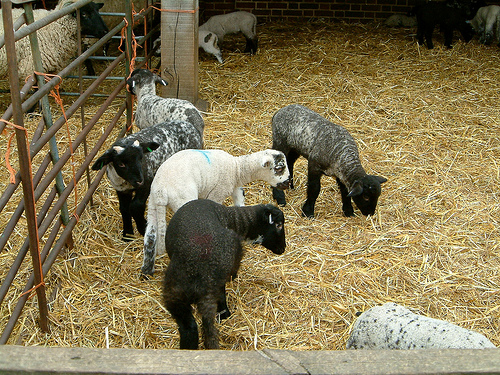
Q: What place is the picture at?
A: It is at the pen.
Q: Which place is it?
A: It is a pen.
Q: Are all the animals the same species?
A: No, there are both sheep and goats.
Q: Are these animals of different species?
A: Yes, they are sheep and goats.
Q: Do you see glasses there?
A: No, there are no glasses.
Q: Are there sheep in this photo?
A: Yes, there is a sheep.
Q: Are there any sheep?
A: Yes, there is a sheep.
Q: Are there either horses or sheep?
A: Yes, there is a sheep.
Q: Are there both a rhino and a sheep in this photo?
A: No, there is a sheep but no rhinos.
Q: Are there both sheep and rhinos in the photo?
A: No, there is a sheep but no rhinos.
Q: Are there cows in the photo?
A: No, there are no cows.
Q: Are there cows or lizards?
A: No, there are no cows or lizards.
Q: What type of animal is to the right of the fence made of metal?
A: The animal is a sheep.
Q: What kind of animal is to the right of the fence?
A: The animal is a sheep.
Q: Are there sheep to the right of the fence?
A: Yes, there is a sheep to the right of the fence.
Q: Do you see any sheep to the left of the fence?
A: No, the sheep is to the right of the fence.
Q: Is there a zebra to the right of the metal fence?
A: No, there is a sheep to the right of the fence.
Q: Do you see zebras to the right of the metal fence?
A: No, there is a sheep to the right of the fence.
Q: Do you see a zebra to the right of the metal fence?
A: No, there is a sheep to the right of the fence.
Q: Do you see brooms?
A: No, there are no brooms.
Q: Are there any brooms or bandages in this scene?
A: No, there are no brooms or bandages.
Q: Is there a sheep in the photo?
A: Yes, there is a sheep.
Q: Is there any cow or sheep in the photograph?
A: Yes, there is a sheep.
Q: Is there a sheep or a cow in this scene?
A: Yes, there is a sheep.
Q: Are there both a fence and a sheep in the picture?
A: Yes, there are both a sheep and a fence.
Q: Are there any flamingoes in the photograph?
A: No, there are no flamingoes.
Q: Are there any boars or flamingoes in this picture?
A: No, there are no flamingoes or boars.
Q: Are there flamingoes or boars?
A: No, there are no flamingoes or boars.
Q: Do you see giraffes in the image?
A: No, there are no giraffes.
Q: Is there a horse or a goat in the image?
A: Yes, there are goats.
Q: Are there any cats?
A: No, there are no cats.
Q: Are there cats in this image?
A: No, there are no cats.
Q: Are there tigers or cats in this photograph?
A: No, there are no cats or tigers.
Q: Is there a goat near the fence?
A: Yes, there are goats near the fence.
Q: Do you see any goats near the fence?
A: Yes, there are goats near the fence.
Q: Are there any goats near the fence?
A: Yes, there are goats near the fence.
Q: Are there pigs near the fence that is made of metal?
A: No, there are goats near the fence.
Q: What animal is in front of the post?
A: The goats are in front of the post.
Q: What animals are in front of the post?
A: The animals are goats.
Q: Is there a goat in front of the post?
A: Yes, there are goats in front of the post.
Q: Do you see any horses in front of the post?
A: No, there are goats in front of the post.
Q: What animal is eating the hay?
A: The goats are eating the hay.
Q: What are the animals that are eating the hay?
A: The animals are goats.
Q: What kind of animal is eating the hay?
A: The animals are goats.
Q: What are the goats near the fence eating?
A: The goats are eating hay.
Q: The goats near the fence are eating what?
A: The goats are eating hay.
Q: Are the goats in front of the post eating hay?
A: Yes, the goats are eating hay.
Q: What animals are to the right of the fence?
A: The animals are goats.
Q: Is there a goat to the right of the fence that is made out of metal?
A: Yes, there are goats to the right of the fence.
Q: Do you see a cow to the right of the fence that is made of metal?
A: No, there are goats to the right of the fence.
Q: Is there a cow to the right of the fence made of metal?
A: No, there are goats to the right of the fence.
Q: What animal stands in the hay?
A: The goats stand in the hay.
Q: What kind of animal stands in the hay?
A: The animals are goats.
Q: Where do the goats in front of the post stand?
A: The goats stand in the hay.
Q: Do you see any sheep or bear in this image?
A: Yes, there is a sheep.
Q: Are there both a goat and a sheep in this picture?
A: Yes, there are both a sheep and a goat.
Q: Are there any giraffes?
A: No, there are no giraffes.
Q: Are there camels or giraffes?
A: No, there are no giraffes or camels.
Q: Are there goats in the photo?
A: Yes, there is a goat.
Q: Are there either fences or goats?
A: Yes, there is a goat.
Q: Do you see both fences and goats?
A: Yes, there are both a goat and a fence.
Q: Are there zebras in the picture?
A: No, there are no zebras.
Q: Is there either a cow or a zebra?
A: No, there are no zebras or cows.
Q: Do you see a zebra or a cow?
A: No, there are no zebras or cows.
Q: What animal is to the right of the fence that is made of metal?
A: The animal is a goat.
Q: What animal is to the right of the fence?
A: The animal is a goat.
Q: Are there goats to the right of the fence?
A: Yes, there is a goat to the right of the fence.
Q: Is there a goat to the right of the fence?
A: Yes, there is a goat to the right of the fence.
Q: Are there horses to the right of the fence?
A: No, there is a goat to the right of the fence.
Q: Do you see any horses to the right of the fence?
A: No, there is a goat to the right of the fence.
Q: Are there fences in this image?
A: Yes, there is a fence.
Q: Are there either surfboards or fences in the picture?
A: Yes, there is a fence.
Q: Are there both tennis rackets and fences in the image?
A: No, there is a fence but no rackets.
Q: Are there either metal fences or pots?
A: Yes, there is a metal fence.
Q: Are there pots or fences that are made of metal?
A: Yes, the fence is made of metal.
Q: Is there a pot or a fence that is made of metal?
A: Yes, the fence is made of metal.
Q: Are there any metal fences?
A: Yes, there is a fence that is made of metal.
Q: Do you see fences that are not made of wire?
A: Yes, there is a fence that is made of metal.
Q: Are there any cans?
A: No, there are no cans.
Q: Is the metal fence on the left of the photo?
A: Yes, the fence is on the left of the image.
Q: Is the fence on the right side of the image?
A: No, the fence is on the left of the image.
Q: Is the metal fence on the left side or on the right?
A: The fence is on the left of the image.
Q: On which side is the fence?
A: The fence is on the left of the image.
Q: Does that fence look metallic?
A: Yes, the fence is metallic.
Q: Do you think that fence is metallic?
A: Yes, the fence is metallic.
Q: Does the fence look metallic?
A: Yes, the fence is metallic.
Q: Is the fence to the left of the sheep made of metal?
A: Yes, the fence is made of metal.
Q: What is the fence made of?
A: The fence is made of metal.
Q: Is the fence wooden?
A: No, the fence is metallic.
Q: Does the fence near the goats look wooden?
A: No, the fence is metallic.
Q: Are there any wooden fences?
A: No, there is a fence but it is metallic.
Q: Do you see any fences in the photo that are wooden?
A: No, there is a fence but it is metallic.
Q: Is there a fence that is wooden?
A: No, there is a fence but it is metallic.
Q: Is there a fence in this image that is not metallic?
A: No, there is a fence but it is metallic.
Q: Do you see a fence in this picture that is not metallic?
A: No, there is a fence but it is metallic.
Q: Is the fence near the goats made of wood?
A: No, the fence is made of metal.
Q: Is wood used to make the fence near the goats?
A: No, the fence is made of metal.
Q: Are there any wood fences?
A: No, there is a fence but it is made of metal.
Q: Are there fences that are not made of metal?
A: No, there is a fence but it is made of metal.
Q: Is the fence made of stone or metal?
A: The fence is made of metal.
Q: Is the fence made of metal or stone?
A: The fence is made of metal.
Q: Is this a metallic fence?
A: Yes, this is a metallic fence.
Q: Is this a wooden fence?
A: No, this is a metallic fence.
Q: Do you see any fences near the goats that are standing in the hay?
A: Yes, there is a fence near the goats.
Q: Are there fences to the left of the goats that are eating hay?
A: Yes, there is a fence to the left of the goats.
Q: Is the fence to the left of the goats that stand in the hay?
A: Yes, the fence is to the left of the goats.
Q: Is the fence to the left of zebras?
A: No, the fence is to the left of the goats.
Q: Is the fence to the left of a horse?
A: No, the fence is to the left of the goat.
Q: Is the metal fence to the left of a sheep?
A: Yes, the fence is to the left of a sheep.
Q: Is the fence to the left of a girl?
A: No, the fence is to the left of a sheep.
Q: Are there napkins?
A: No, there are no napkins.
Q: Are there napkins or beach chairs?
A: No, there are no napkins or beach chairs.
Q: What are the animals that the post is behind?
A: The animals are goats.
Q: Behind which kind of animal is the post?
A: The post is behind the goats.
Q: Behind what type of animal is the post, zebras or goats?
A: The post is behind goats.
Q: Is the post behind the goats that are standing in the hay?
A: Yes, the post is behind the goats.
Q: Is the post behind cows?
A: No, the post is behind the goats.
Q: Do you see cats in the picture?
A: No, there are no cats.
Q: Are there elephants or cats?
A: No, there are no cats or elephants.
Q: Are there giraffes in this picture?
A: No, there are no giraffes.